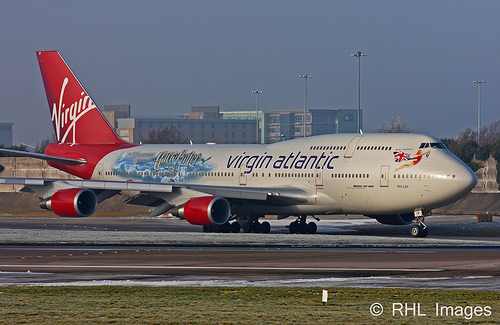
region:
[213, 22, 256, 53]
part of the sky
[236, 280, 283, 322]
part of some grass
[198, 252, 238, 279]
part of a runway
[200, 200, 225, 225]
part of an engine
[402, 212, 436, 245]
part of a wheel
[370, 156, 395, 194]
part of a door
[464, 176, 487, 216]
tip of a plane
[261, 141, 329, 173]
side of the plane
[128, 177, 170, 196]
edge of a wing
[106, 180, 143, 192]
part of a wing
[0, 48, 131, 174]
the tail of the plane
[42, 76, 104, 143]
white writing on the tail of the plane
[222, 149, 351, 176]
blue writing on the plane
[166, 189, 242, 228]
the engine of the plane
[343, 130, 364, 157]
a door on the plane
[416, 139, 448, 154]
the windows of the cockpit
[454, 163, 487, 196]
the nose of the plane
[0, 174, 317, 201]
the wing of the plane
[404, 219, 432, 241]
the front wheel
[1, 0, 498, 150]
a gray and blue sky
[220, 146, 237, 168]
a letter is written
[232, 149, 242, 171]
a letter is written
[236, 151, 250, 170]
a letter is written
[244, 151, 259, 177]
a letter is written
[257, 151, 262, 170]
a letter is written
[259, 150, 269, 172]
a letter is written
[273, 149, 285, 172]
a letter is written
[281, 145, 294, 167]
a letter is written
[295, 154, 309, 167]
a letter is written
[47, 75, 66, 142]
a letter is written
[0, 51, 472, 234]
a jumbo passenger jet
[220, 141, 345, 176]
the Virgin Atlantic logo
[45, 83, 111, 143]
The Virgin logo on the tail of a plane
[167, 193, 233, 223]
a red and silver colored jet engine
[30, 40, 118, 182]
the red and white tail of a plane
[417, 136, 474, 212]
the cockpit of a passenger plane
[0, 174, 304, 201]
the right wing of a plane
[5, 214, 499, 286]
a concrete runway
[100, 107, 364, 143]
some buildings standing in the distance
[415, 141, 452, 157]
the front windshield of a plane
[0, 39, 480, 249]
Plane is from Virgin Atlantic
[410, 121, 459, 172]
Cockpit of plane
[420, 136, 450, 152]
Small windows in cockpit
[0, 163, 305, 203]
Left wing of train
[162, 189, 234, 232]
Engine on right is red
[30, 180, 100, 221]
Engine on left is red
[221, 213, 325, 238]
Wheels of plane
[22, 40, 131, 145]
Vertical stabilizer has white letters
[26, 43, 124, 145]
White letters says Virgin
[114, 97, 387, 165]
Buildings behind plane